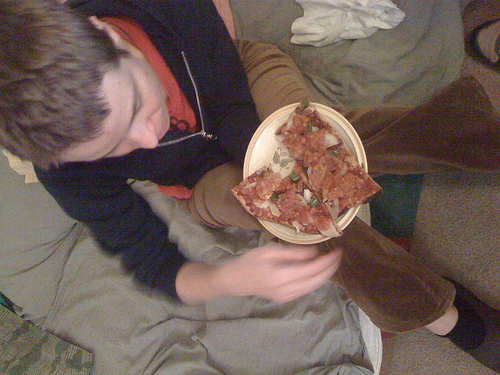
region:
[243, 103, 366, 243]
A yellow food plate in a man's hand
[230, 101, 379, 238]
Two slices of meat pizza on the plate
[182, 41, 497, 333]
Brown trousers of the man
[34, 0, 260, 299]
Black sweater the man is wearing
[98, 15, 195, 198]
Red tshirt the man is wearing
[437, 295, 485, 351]
Black loafer the man is wearing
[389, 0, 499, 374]
Brown rug on the floor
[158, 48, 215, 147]
Zip on the black sweater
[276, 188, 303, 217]
One of the meat chunks on the pizza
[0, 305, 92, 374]
A green abd grey cushion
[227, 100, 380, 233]
food on the plate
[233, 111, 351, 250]
brown food on plate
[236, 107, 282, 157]
edge of the plate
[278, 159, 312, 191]
green topping on plate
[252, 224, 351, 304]
hand of the person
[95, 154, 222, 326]
arm of the person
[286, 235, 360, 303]
fingers on the person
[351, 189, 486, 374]
leg of the person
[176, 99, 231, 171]
zipper on the jacket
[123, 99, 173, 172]
nose of the person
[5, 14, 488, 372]
this is a man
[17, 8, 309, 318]
man wearing a blue jacket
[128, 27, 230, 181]
zipper on the jacket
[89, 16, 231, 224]
man wearing an orange shirt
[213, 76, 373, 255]
man holding a plate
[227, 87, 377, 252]
pizza on the plate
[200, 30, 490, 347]
wearing brown pants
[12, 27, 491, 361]
man is sitting down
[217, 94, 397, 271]
the plate is tan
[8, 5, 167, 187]
brown hair on man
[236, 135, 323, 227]
pizza with sauce and cheese on it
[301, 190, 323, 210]
pepper green and fresh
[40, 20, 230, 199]
young white male staring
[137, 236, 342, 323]
motion blurred hand with shirt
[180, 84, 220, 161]
zipper pulled halfway down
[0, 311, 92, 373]
camo piece of cotton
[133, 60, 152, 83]
pimple on side of face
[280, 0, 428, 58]
towel on the couch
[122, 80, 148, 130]
eye brow with eyelashes and eyelid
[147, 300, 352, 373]
messy sheets smashed together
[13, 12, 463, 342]
this guy is eating some food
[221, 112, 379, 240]
this is pizza on a plate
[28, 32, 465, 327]
this picture was taken from above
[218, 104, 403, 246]
the guy has four pieces of pizza on his plate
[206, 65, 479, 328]
he has on brown pants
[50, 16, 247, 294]
his jacket is blue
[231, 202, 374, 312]
his right hand is about to touch the plate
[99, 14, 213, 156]
he has on a red shirt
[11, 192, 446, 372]
he is sitting on a messy bed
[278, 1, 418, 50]
a white shirt in the picture